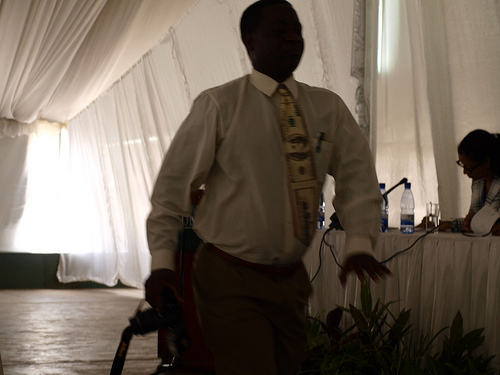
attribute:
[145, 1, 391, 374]
man — dancing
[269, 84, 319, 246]
tie — hundred dollar bill, yellow, neck tie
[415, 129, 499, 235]
woman — writing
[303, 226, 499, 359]
table — event table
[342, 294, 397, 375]
plant — green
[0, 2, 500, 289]
tent — large, white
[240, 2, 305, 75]
head — bald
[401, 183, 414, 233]
bottle — plastic, water, water bottle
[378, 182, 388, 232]
bottle — plastic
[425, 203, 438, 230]
glass — clear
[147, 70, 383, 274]
shirt — white, long sleeved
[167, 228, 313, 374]
pants — tan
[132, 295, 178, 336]
camera — black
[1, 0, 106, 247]
curtain — white, hanging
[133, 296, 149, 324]
strap — black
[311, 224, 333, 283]
cable — black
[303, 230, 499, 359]
cloth — white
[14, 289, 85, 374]
light — reflecting